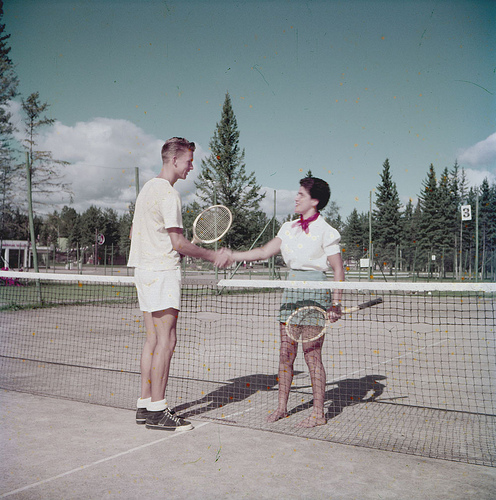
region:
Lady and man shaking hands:
[92, 125, 397, 421]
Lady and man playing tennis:
[112, 127, 384, 421]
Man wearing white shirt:
[97, 110, 213, 430]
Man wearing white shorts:
[119, 115, 211, 338]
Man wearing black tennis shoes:
[117, 380, 193, 443]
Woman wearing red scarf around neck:
[254, 163, 373, 308]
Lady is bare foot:
[250, 370, 342, 442]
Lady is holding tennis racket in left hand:
[277, 184, 388, 353]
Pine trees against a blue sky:
[337, 134, 453, 223]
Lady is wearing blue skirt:
[270, 258, 357, 343]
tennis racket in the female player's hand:
[280, 295, 403, 342]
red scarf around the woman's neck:
[289, 212, 329, 231]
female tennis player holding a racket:
[235, 158, 385, 428]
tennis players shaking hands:
[121, 132, 387, 429]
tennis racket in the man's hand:
[177, 197, 229, 252]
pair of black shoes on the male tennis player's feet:
[134, 393, 190, 427]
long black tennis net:
[0, 263, 489, 414]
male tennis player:
[121, 120, 231, 441]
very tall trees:
[1, 13, 75, 301]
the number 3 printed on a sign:
[457, 206, 474, 220]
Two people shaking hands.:
[126, 122, 361, 445]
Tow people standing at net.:
[122, 132, 378, 455]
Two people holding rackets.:
[117, 121, 386, 451]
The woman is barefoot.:
[234, 159, 421, 443]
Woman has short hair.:
[240, 169, 398, 431]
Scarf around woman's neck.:
[246, 166, 402, 440]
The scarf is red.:
[249, 164, 404, 446]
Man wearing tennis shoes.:
[117, 126, 239, 449]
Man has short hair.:
[115, 126, 231, 269]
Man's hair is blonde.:
[118, 126, 234, 280]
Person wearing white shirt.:
[135, 187, 169, 242]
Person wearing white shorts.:
[116, 231, 202, 337]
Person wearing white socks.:
[134, 386, 189, 430]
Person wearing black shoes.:
[117, 364, 216, 455]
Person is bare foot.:
[261, 388, 368, 497]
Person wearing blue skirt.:
[284, 275, 359, 338]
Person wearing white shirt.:
[281, 236, 331, 281]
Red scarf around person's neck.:
[287, 207, 336, 255]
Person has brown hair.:
[306, 177, 323, 206]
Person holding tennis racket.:
[295, 293, 348, 344]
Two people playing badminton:
[102, 121, 358, 475]